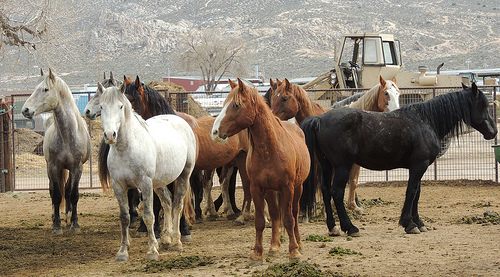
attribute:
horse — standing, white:
[22, 71, 89, 236]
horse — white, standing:
[97, 82, 197, 259]